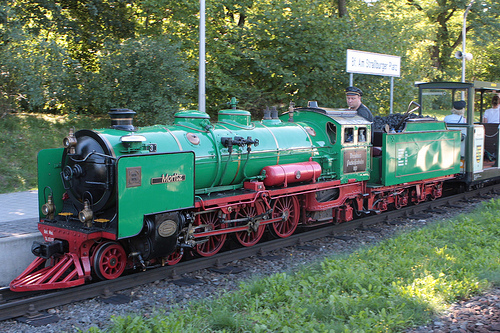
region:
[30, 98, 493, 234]
green children's train on track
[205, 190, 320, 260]
train has red wheels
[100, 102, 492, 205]
green frame on engine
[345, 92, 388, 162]
man sits in train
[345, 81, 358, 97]
man has green cap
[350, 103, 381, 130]
man has green shirt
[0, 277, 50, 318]
train on black track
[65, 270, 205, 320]
grey gravel around track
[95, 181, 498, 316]
green grass near track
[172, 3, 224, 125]
flag pole behind train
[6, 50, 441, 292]
this is a train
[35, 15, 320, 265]
this is red and green train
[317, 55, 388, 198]
this is a person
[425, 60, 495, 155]
this is a person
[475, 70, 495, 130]
this is a person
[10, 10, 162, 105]
this is green vegetation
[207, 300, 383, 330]
this is green vegetation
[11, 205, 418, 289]
this is the rail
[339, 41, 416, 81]
this is a sign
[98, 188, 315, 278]
these are the wheels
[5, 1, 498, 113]
green leaves on trees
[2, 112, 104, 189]
hill of green grass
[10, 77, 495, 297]
red and green train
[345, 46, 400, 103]
sign on two poles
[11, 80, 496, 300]
miniature train on tracks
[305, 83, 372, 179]
engineer operating small train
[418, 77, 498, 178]
train car for passengers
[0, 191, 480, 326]
rail of train track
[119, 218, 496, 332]
green grass and weeds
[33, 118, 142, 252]
the front of a train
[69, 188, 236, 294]
the wheelst of a train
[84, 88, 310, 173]
the topt of a train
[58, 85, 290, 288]
a green little train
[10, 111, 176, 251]
the front of a little train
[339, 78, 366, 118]
the head of a man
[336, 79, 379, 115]
the nose of a man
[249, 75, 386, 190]
a man on a train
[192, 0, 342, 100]
green leaves on trees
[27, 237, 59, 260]
black bumper guard on the front of train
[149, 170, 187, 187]
word written of the side of train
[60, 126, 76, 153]
single head light on the top front of train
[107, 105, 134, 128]
small black smoke stack on top of train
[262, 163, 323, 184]
red cylindrical with gauge on side of train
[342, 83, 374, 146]
man with hat driving the train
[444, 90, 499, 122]
two people riding in window less car of train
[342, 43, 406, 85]
sign on the side of tracks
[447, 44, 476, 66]
loud speakers on a pole on the side of road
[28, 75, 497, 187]
people riding on a miniature train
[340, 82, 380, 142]
conductor of the train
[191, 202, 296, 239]
train wheel rims are red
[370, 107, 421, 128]
coal behind the conductor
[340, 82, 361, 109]
conductor is wearing a hat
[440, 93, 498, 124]
passengers on the train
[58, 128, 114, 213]
front of engin is black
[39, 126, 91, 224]
lights on the front of the train